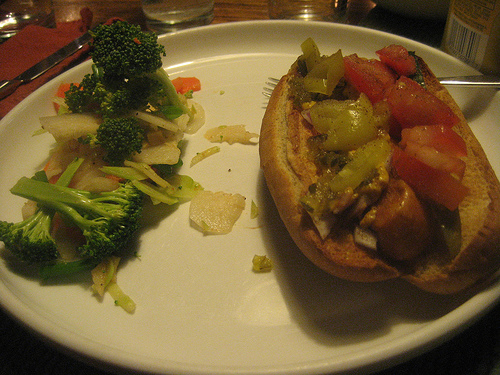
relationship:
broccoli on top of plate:
[5, 173, 148, 265] [0, 16, 498, 375]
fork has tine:
[256, 68, 499, 112] [266, 74, 282, 84]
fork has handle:
[256, 68, 499, 112] [434, 67, 500, 95]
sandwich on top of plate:
[255, 34, 499, 307] [0, 16, 498, 375]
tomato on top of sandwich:
[376, 42, 419, 75] [255, 34, 499, 307]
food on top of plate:
[202, 121, 261, 148] [0, 16, 498, 375]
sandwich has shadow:
[255, 34, 499, 307] [252, 163, 499, 343]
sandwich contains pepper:
[255, 34, 499, 307] [298, 33, 323, 71]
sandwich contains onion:
[255, 34, 499, 307] [351, 221, 380, 253]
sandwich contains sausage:
[255, 34, 499, 307] [363, 172, 435, 268]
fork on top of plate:
[256, 68, 499, 112] [0, 16, 498, 375]